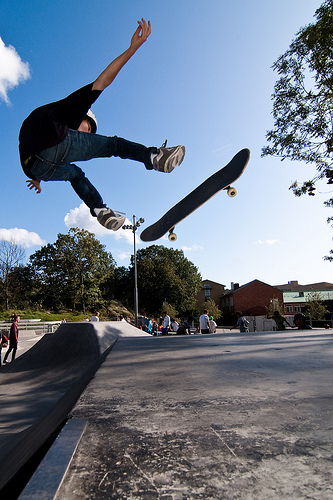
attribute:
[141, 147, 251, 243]
skateboard — black, white, wooden, in mid-air, in air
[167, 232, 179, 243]
wheel — white, yellow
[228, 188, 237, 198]
wheel — white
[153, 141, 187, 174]
shoe — grey, white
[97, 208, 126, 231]
shoe — grey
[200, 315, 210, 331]
shirt — white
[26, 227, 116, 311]
tree — large, green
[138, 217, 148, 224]
light — tall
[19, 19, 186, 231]
skater — in mid-air, skateboarding, in air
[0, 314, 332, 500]
park — concrete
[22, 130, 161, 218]
jeans — blue, green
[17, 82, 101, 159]
shirt — short sleeve, black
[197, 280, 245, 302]
house — brick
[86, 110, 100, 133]
helmet — white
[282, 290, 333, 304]
roof — light colored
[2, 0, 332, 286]
sky — blue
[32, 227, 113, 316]
leaves — green